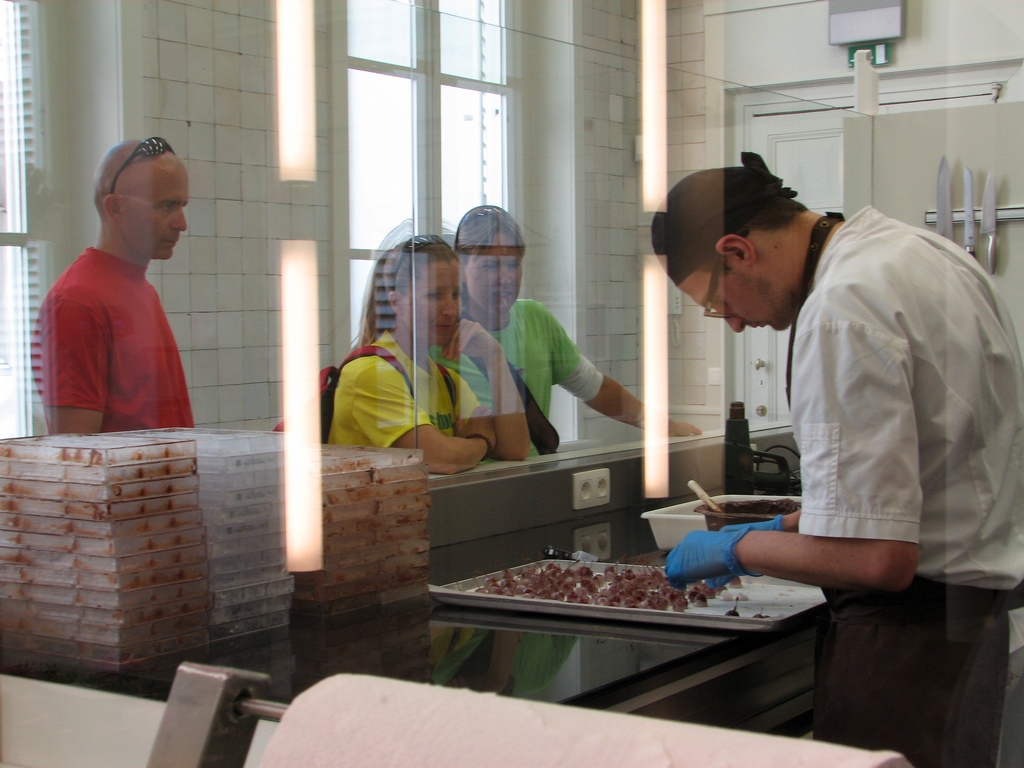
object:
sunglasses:
[704, 267, 731, 319]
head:
[91, 138, 187, 260]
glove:
[665, 514, 785, 590]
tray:
[425, 558, 827, 632]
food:
[476, 562, 742, 610]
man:
[651, 151, 1023, 768]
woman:
[318, 235, 529, 475]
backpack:
[273, 346, 456, 443]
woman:
[435, 206, 701, 467]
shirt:
[432, 299, 605, 464]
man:
[28, 136, 192, 435]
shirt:
[33, 247, 194, 433]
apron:
[651, 151, 1021, 765]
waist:
[833, 575, 1024, 626]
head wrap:
[652, 151, 799, 286]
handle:
[687, 480, 723, 513]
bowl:
[641, 495, 800, 553]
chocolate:
[695, 497, 802, 530]